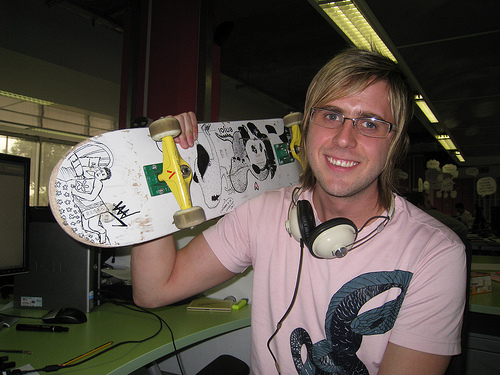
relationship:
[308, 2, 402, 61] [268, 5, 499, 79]
lights on ceiling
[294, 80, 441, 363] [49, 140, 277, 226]
man holding skateboard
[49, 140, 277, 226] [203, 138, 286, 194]
skateboard has doodles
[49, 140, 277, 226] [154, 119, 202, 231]
skateboard has wheels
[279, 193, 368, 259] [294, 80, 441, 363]
headphones on man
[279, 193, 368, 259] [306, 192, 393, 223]
headphones around neck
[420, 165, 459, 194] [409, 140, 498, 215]
drawings on wall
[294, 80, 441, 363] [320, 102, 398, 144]
man wearing glasses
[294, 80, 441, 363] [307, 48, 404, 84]
man has hair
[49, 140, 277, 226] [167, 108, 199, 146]
skateboard in hand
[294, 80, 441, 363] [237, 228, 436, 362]
man wearing shirt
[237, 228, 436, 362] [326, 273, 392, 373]
shirt has snake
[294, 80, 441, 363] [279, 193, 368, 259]
man wearing headphones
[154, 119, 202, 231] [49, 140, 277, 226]
wheels on skateboard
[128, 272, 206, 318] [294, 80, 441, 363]
elbow of man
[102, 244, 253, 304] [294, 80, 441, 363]
arm on man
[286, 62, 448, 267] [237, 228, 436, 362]
skateboarder wearing shirt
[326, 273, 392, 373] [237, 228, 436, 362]
snake on shirt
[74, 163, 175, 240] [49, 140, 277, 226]
drawings on skateboard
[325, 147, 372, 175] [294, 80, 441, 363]
mouth on person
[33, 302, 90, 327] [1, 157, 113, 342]
mouse by computer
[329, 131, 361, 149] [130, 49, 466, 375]
nose on man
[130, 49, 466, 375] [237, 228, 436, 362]
man wearing shirt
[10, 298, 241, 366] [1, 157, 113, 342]
desk has computer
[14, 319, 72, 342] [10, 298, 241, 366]
marker on desk